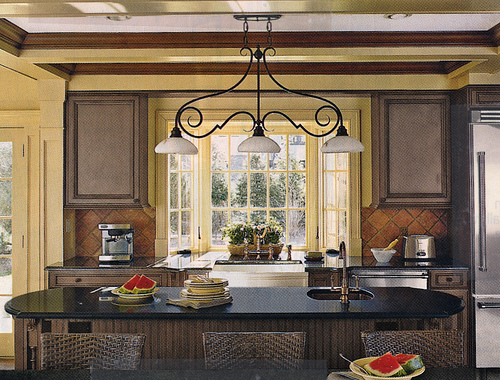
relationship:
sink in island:
[306, 237, 376, 309] [3, 280, 464, 370]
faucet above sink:
[337, 242, 349, 304] [309, 285, 366, 298]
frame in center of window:
[210, 135, 305, 247] [162, 113, 377, 272]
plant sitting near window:
[233, 218, 283, 240] [166, 119, 357, 256]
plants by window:
[223, 222, 285, 257] [167, 125, 348, 250]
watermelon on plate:
[130, 275, 157, 293] [111, 287, 156, 298]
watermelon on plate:
[117, 275, 139, 295] [111, 287, 156, 298]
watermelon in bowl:
[369, 350, 409, 376] [344, 351, 426, 378]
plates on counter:
[158, 261, 235, 318] [12, 265, 459, 335]